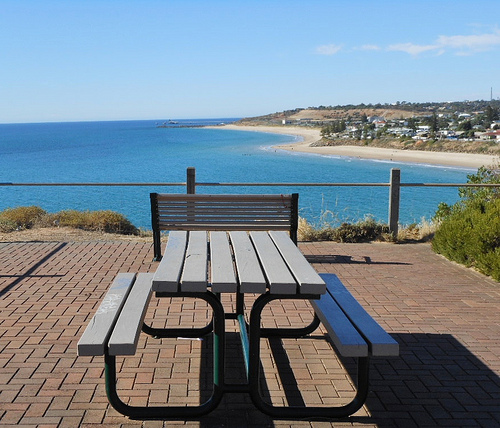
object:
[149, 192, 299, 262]
bench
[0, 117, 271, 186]
water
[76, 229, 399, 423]
table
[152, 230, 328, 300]
top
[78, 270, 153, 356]
seat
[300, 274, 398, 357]
seat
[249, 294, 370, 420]
pipe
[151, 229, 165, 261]
leg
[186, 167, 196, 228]
post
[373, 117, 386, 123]
houses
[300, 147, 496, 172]
beach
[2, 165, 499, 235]
fence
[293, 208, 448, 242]
bushes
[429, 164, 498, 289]
bushes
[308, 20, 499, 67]
clouds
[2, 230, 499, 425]
balcony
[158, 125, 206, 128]
rocks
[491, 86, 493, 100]
tower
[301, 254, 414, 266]
shadow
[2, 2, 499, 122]
sky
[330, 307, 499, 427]
shadow